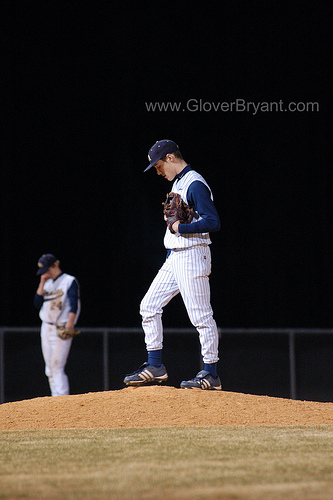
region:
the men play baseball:
[40, 137, 222, 399]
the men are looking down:
[38, 140, 223, 400]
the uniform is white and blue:
[34, 136, 220, 405]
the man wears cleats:
[121, 370, 219, 387]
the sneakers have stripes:
[122, 371, 222, 389]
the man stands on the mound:
[0, 386, 331, 498]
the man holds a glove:
[161, 197, 193, 234]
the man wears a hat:
[141, 138, 178, 176]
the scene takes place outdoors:
[2, 0, 330, 499]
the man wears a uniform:
[124, 140, 221, 386]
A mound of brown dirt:
[3, 388, 332, 431]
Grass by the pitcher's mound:
[2, 431, 332, 498]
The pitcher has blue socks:
[146, 348, 217, 372]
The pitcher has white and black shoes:
[122, 372, 221, 389]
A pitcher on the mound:
[125, 139, 222, 390]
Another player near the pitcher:
[34, 253, 78, 394]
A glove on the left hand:
[164, 192, 186, 226]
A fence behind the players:
[1, 327, 330, 403]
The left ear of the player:
[166, 152, 176, 161]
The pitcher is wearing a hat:
[139, 140, 180, 169]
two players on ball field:
[32, 135, 228, 397]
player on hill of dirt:
[126, 133, 234, 396]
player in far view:
[32, 247, 84, 397]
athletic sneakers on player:
[120, 368, 223, 393]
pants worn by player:
[143, 248, 227, 361]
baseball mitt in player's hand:
[161, 192, 196, 224]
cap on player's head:
[143, 136, 182, 171]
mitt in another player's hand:
[58, 319, 77, 342]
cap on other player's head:
[34, 252, 61, 272]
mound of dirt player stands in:
[2, 390, 332, 430]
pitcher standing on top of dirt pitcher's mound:
[120, 134, 329, 437]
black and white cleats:
[115, 360, 225, 394]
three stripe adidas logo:
[134, 364, 154, 381]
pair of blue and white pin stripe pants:
[134, 245, 225, 372]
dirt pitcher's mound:
[4, 387, 332, 436]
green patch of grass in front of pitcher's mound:
[3, 428, 330, 496]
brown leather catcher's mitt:
[153, 189, 193, 234]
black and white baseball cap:
[136, 135, 184, 175]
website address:
[137, 91, 322, 121]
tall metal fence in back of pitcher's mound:
[4, 319, 331, 399]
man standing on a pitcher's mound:
[108, 119, 229, 402]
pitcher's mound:
[0, 383, 326, 499]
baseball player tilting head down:
[30, 239, 88, 405]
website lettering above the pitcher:
[137, 92, 323, 119]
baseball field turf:
[0, 427, 329, 494]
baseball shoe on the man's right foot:
[121, 362, 169, 387]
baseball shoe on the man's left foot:
[179, 364, 224, 391]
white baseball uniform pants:
[137, 238, 221, 370]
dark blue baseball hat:
[142, 132, 179, 174]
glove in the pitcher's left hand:
[158, 185, 198, 231]